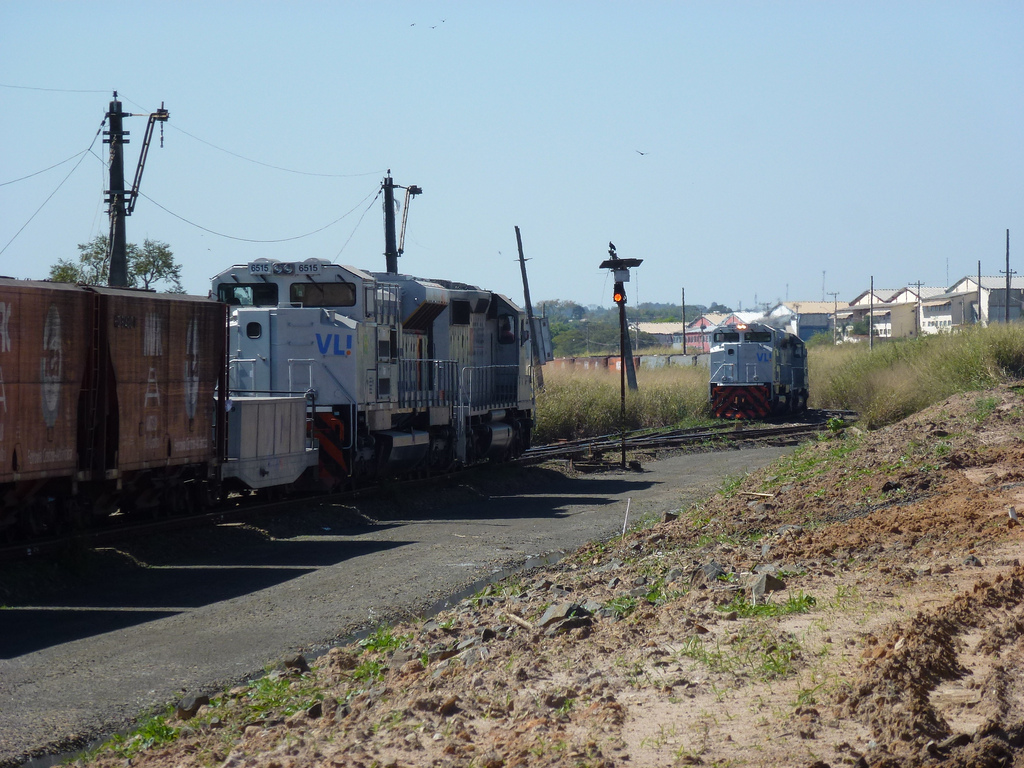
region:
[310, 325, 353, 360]
blue letters on the front of the train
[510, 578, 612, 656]
rock on the ground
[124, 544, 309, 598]
shadows on the ground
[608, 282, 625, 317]
orange light on the post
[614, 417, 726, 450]
tracks in between the two trains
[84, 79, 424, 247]
electrical wires connected to the poles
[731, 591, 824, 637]
patches of grass in the dirt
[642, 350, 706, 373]
train cars in the field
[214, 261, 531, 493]
a white train engine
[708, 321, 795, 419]
a white train engine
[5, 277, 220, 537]
a red box car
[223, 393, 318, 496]
a white coal car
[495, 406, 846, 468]
a set of train tracks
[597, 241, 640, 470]
an electric train signal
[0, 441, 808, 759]
a blacktopped paved road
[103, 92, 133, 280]
a telephone pole in distance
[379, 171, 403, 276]
a telephone pole in distance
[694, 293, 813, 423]
Train on the tracks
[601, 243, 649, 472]
Signal light by the tracks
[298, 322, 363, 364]
Blue lettering on the train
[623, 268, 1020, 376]
Buildings in the distance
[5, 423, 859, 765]
Road beside the tracks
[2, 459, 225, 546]
Wheels on the train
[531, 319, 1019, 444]
Tall grass by the tracks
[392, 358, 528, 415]
Railing on the train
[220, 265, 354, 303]
Wipers on the train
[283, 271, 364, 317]
Window on the train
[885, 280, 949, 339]
a building in a city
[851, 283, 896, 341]
a building in a city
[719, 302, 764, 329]
a building in a city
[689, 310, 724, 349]
a building in a city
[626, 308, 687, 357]
a building in a city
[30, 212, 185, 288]
a tree in a field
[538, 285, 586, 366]
a tree in the woods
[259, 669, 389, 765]
a patch of dirt with some grass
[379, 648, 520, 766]
a patch of dirt with some grass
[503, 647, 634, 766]
a patch of dirt with some grass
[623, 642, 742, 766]
a patch of dirt with some grass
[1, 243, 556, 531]
train on railroad tracks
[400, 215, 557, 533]
a train car on the track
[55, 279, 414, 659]
a train car on the track